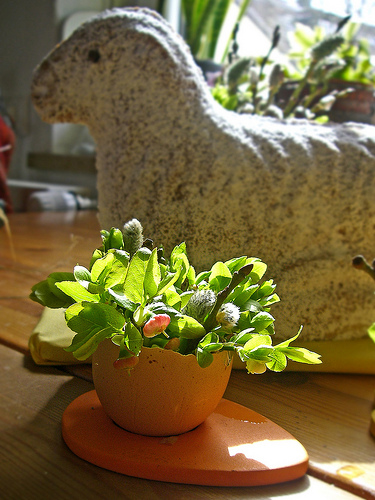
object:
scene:
[4, 6, 374, 498]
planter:
[90, 335, 231, 437]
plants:
[31, 224, 320, 376]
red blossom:
[144, 309, 173, 343]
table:
[4, 213, 370, 470]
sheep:
[33, 10, 373, 345]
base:
[61, 391, 310, 480]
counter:
[5, 220, 92, 372]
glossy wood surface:
[23, 221, 78, 257]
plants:
[188, 6, 372, 124]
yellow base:
[31, 303, 371, 372]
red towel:
[4, 118, 18, 174]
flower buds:
[186, 283, 239, 326]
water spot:
[334, 458, 361, 485]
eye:
[88, 46, 104, 65]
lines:
[232, 122, 373, 194]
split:
[308, 467, 374, 499]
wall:
[4, 4, 57, 152]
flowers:
[142, 292, 241, 336]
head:
[31, 12, 213, 134]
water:
[218, 399, 272, 434]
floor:
[5, 353, 370, 489]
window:
[229, 6, 374, 73]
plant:
[299, 17, 374, 86]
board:
[2, 348, 357, 497]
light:
[236, 442, 372, 500]